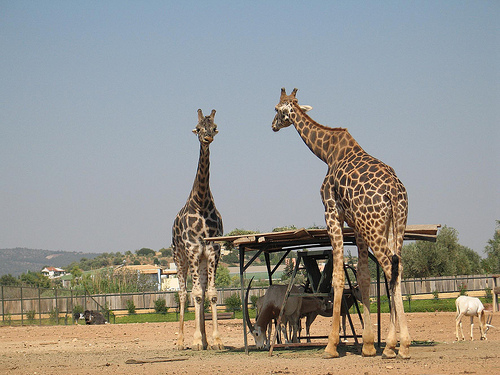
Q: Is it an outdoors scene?
A: Yes, it is outdoors.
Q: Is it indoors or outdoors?
A: It is outdoors.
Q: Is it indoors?
A: No, it is outdoors.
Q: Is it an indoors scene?
A: No, it is outdoors.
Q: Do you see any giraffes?
A: Yes, there are giraffes.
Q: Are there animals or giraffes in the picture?
A: Yes, there are giraffes.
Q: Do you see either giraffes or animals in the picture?
A: Yes, there are giraffes.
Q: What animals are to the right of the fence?
A: The animals are giraffes.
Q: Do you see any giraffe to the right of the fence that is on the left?
A: Yes, there are giraffes to the right of the fence.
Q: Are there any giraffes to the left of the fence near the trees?
A: No, the giraffes are to the right of the fence.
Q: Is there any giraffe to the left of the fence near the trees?
A: No, the giraffes are to the right of the fence.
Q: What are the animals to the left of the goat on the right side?
A: The animals are giraffes.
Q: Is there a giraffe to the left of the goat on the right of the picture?
A: Yes, there are giraffes to the left of the goat.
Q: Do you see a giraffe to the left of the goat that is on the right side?
A: Yes, there are giraffes to the left of the goat.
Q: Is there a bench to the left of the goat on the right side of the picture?
A: No, there are giraffes to the left of the goat.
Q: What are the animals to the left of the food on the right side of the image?
A: The animals are giraffes.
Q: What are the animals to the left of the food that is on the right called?
A: The animals are giraffes.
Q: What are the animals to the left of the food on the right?
A: The animals are giraffes.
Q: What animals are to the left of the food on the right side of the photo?
A: The animals are giraffes.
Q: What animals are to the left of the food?
A: The animals are giraffes.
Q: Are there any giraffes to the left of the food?
A: Yes, there are giraffes to the left of the food.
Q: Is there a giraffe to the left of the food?
A: Yes, there are giraffes to the left of the food.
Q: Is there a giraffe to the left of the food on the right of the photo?
A: Yes, there are giraffes to the left of the food.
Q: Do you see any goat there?
A: Yes, there are goats.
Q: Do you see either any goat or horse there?
A: Yes, there are goats.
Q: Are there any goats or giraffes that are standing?
A: Yes, the goats are standing.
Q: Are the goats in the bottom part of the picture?
A: Yes, the goats are in the bottom of the image.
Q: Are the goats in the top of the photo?
A: No, the goats are in the bottom of the image.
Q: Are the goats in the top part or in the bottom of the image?
A: The goats are in the bottom of the image.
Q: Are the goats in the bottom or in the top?
A: The goats are in the bottom of the image.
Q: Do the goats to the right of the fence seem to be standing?
A: Yes, the goats are standing.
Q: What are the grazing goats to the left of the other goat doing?
A: The goats are standing.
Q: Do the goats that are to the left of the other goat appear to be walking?
A: No, the goats are standing.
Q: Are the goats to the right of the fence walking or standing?
A: The goats are standing.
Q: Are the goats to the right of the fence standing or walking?
A: The goats are standing.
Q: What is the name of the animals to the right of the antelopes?
A: The animals are goats.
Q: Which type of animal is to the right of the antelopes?
A: The animals are goats.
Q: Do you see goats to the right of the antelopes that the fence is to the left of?
A: Yes, there are goats to the right of the antelopes.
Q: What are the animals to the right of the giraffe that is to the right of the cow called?
A: The animals are goats.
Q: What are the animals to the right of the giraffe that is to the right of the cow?
A: The animals are goats.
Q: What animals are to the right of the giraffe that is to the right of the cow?
A: The animals are goats.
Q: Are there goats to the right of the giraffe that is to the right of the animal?
A: Yes, there are goats to the right of the giraffe.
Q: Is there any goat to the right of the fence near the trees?
A: Yes, there are goats to the right of the fence.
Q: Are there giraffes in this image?
A: Yes, there is a giraffe.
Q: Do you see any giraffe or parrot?
A: Yes, there is a giraffe.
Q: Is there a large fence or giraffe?
A: Yes, there is a large giraffe.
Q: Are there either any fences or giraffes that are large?
A: Yes, the giraffe is large.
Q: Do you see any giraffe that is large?
A: Yes, there is a large giraffe.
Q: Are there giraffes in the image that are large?
A: Yes, there is a giraffe that is large.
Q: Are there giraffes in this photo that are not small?
A: Yes, there is a large giraffe.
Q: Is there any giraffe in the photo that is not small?
A: Yes, there is a large giraffe.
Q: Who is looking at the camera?
A: The giraffe is looking at the camera.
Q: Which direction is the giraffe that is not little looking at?
A: The giraffe is looking at the camera.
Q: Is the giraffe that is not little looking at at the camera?
A: Yes, the giraffe is looking at the camera.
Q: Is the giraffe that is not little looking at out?
A: No, the giraffe is looking at the camera.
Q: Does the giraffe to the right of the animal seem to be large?
A: Yes, the giraffe is large.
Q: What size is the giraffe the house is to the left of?
A: The giraffe is large.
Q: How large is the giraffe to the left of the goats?
A: The giraffe is large.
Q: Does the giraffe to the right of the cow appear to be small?
A: No, the giraffe is large.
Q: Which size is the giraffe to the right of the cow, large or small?
A: The giraffe is large.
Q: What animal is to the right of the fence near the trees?
A: The animal is a giraffe.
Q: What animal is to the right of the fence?
A: The animal is a giraffe.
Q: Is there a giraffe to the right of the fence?
A: Yes, there is a giraffe to the right of the fence.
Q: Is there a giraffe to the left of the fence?
A: No, the giraffe is to the right of the fence.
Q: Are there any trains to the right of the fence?
A: No, there is a giraffe to the right of the fence.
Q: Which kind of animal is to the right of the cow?
A: The animal is a giraffe.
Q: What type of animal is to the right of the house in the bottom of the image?
A: The animal is a giraffe.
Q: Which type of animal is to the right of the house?
A: The animal is a giraffe.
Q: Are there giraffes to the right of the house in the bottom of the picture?
A: Yes, there is a giraffe to the right of the house.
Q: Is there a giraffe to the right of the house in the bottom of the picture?
A: Yes, there is a giraffe to the right of the house.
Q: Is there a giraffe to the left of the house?
A: No, the giraffe is to the right of the house.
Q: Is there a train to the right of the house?
A: No, there is a giraffe to the right of the house.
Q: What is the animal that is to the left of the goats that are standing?
A: The animal is a giraffe.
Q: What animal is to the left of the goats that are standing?
A: The animal is a giraffe.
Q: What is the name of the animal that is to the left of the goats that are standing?
A: The animal is a giraffe.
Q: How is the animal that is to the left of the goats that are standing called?
A: The animal is a giraffe.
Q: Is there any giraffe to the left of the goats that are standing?
A: Yes, there is a giraffe to the left of the goats.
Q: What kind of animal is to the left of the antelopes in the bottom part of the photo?
A: The animal is a giraffe.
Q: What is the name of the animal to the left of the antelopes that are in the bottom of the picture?
A: The animal is a giraffe.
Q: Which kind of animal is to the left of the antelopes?
A: The animal is a giraffe.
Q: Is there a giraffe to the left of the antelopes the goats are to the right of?
A: Yes, there is a giraffe to the left of the antelopes.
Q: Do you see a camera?
A: Yes, there is a camera.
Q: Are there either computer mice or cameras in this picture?
A: Yes, there is a camera.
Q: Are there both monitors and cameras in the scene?
A: No, there is a camera but no monitors.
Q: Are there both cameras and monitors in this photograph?
A: No, there is a camera but no monitors.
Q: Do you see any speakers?
A: No, there are no speakers.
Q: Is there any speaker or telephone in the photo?
A: No, there are no speakers or phones.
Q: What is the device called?
A: The device is a camera.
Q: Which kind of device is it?
A: The device is a camera.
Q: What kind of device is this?
A: This is a camera.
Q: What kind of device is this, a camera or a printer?
A: This is a camera.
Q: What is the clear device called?
A: The device is a camera.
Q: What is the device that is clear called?
A: The device is a camera.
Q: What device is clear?
A: The device is a camera.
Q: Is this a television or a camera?
A: This is a camera.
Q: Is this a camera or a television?
A: This is a camera.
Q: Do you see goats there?
A: Yes, there is a goat.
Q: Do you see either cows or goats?
A: Yes, there is a goat.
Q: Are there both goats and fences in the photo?
A: Yes, there are both a goat and a fence.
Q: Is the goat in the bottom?
A: Yes, the goat is in the bottom of the image.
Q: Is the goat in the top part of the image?
A: No, the goat is in the bottom of the image.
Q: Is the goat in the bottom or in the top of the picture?
A: The goat is in the bottom of the image.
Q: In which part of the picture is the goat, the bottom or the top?
A: The goat is in the bottom of the image.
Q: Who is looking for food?
A: The goat is looking for food.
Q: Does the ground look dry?
A: Yes, the ground is dry.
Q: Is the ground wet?
A: No, the ground is dry.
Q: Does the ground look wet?
A: No, the ground is dry.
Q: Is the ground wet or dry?
A: The ground is dry.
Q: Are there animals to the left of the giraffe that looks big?
A: Yes, there is an animal to the left of the giraffe.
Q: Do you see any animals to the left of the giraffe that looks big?
A: Yes, there is an animal to the left of the giraffe.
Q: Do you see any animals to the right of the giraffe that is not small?
A: No, the animal is to the left of the giraffe.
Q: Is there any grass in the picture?
A: Yes, there is grass.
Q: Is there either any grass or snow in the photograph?
A: Yes, there is grass.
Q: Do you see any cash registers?
A: No, there are no cash registers.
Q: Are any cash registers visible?
A: No, there are no cash registers.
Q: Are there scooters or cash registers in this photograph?
A: No, there are no cash registers or scooters.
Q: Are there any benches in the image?
A: No, there are no benches.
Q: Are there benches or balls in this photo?
A: No, there are no benches or balls.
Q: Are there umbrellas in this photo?
A: No, there are no umbrellas.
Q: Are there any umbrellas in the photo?
A: No, there are no umbrellas.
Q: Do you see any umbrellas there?
A: No, there are no umbrellas.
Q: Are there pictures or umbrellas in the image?
A: No, there are no umbrellas or pictures.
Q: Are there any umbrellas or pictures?
A: No, there are no umbrellas or pictures.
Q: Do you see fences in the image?
A: Yes, there is a fence.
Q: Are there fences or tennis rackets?
A: Yes, there is a fence.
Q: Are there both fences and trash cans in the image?
A: No, there is a fence but no trash cans.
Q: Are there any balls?
A: No, there are no balls.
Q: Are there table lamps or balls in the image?
A: No, there are no balls or table lamps.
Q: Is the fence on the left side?
A: Yes, the fence is on the left of the image.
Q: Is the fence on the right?
A: No, the fence is on the left of the image.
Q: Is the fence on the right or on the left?
A: The fence is on the left of the image.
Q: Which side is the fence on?
A: The fence is on the left of the image.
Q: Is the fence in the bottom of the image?
A: Yes, the fence is in the bottom of the image.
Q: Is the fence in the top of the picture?
A: No, the fence is in the bottom of the image.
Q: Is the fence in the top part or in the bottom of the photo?
A: The fence is in the bottom of the image.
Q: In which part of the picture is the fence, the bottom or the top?
A: The fence is in the bottom of the image.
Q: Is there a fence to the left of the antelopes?
A: Yes, there is a fence to the left of the antelopes.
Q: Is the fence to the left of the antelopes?
A: Yes, the fence is to the left of the antelopes.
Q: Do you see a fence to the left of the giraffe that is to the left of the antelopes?
A: Yes, there is a fence to the left of the giraffe.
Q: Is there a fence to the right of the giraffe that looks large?
A: No, the fence is to the left of the giraffe.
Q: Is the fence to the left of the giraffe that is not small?
A: Yes, the fence is to the left of the giraffe.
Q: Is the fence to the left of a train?
A: No, the fence is to the left of the giraffe.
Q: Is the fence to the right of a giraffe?
A: No, the fence is to the left of a giraffe.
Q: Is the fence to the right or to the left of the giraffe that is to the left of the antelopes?
A: The fence is to the left of the giraffe.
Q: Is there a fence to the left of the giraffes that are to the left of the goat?
A: Yes, there is a fence to the left of the giraffes.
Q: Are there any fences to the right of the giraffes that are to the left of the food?
A: No, the fence is to the left of the giraffes.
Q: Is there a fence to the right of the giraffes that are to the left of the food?
A: No, the fence is to the left of the giraffes.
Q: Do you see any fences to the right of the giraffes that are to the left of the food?
A: No, the fence is to the left of the giraffes.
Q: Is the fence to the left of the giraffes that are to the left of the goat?
A: Yes, the fence is to the left of the giraffes.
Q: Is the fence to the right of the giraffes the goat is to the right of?
A: No, the fence is to the left of the giraffes.